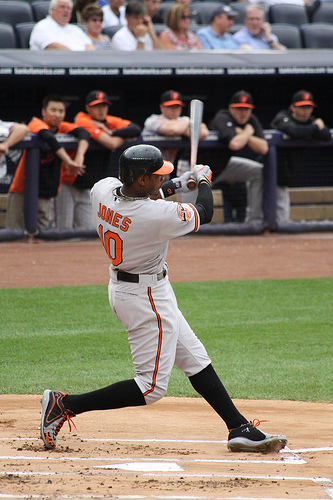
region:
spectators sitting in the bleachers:
[1, 0, 331, 51]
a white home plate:
[94, 461, 182, 473]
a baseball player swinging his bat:
[41, 98, 286, 455]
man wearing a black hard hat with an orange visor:
[119, 144, 174, 186]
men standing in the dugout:
[1, 87, 332, 229]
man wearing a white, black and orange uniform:
[62, 177, 246, 425]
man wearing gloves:
[161, 162, 210, 199]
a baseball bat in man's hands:
[187, 98, 204, 191]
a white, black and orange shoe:
[40, 386, 76, 452]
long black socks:
[60, 379, 145, 413]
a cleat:
[34, 384, 72, 451]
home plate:
[93, 455, 186, 477]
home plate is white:
[93, 459, 187, 474]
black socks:
[191, 375, 241, 416]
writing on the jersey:
[93, 203, 137, 232]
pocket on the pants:
[114, 292, 134, 299]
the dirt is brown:
[125, 421, 196, 433]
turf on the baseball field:
[285, 413, 318, 441]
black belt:
[118, 272, 137, 284]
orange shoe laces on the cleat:
[250, 416, 266, 426]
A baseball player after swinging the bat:
[32, 95, 301, 455]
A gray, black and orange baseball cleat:
[32, 383, 74, 455]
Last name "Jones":
[93, 200, 133, 236]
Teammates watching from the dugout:
[11, 81, 332, 183]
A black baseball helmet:
[108, 141, 174, 188]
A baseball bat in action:
[184, 93, 206, 192]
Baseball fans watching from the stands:
[9, 0, 314, 62]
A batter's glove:
[187, 159, 217, 185]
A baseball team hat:
[288, 85, 318, 108]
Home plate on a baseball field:
[86, 452, 202, 485]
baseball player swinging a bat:
[36, 74, 286, 454]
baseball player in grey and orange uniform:
[38, 92, 291, 452]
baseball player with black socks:
[36, 92, 292, 454]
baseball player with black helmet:
[99, 135, 178, 202]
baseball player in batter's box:
[39, 82, 291, 459]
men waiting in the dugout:
[3, 77, 326, 203]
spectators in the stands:
[25, 0, 277, 52]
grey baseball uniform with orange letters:
[32, 170, 289, 456]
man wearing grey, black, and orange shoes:
[37, 383, 288, 465]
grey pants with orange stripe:
[97, 257, 218, 397]